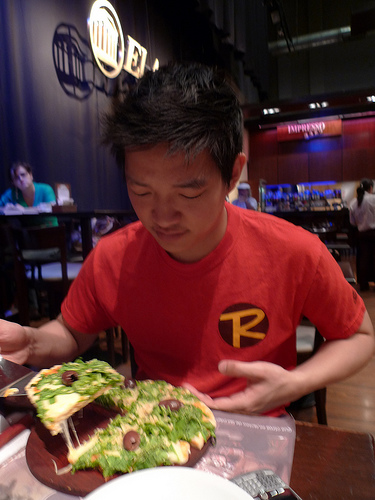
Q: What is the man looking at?
A: Food.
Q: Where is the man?
A: Restaurant.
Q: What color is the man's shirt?
A: Red.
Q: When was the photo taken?
A: When the man was about to eat.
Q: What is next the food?
A: A phone.